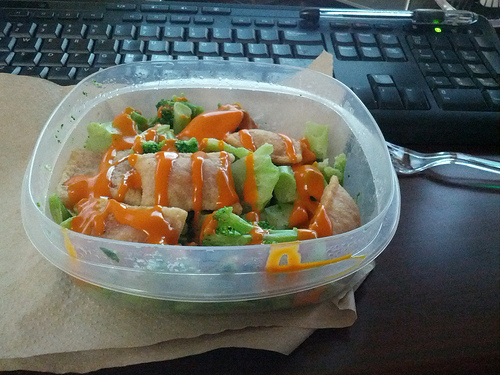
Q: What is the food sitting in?
A: A plastic container.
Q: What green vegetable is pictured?
A: Broccoli.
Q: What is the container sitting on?
A: A desk.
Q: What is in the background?
A: A keyboard.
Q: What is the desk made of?
A: Wood.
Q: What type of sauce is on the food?
A: Orange sauce.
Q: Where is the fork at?
A: To the right of the container.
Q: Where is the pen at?
A: Sitting on the keyboard.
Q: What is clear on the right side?
A: Fork.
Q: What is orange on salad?
A: Dressing.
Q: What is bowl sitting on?
A: Table.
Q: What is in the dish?
A: Food.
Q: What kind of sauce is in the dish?
A: French dressing.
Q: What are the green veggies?
A: Broccoli.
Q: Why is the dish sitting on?
A: Napkins.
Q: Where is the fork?
A: Right of the dish.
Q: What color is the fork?
A: Clear plastic.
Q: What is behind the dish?
A: Keyboard.